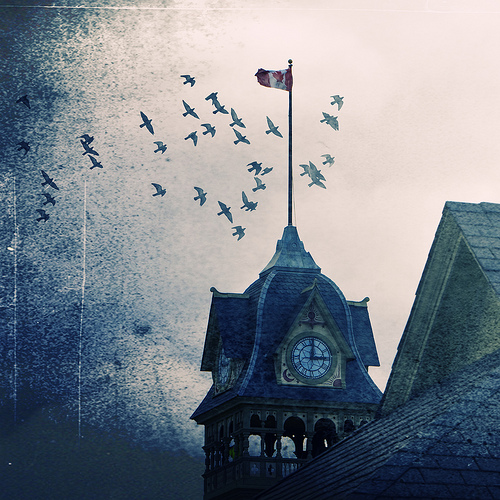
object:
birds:
[329, 94, 346, 111]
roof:
[370, 200, 500, 423]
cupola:
[187, 221, 388, 428]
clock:
[214, 336, 234, 397]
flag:
[253, 68, 295, 93]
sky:
[0, 0, 500, 500]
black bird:
[41, 169, 60, 190]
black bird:
[40, 193, 56, 207]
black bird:
[35, 208, 49, 223]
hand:
[310, 335, 315, 363]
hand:
[303, 356, 327, 361]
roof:
[251, 350, 500, 500]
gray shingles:
[428, 451, 483, 473]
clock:
[280, 297, 342, 388]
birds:
[180, 74, 197, 87]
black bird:
[150, 182, 167, 197]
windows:
[280, 415, 308, 460]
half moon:
[283, 368, 295, 382]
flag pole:
[287, 59, 294, 226]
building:
[187, 225, 387, 500]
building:
[258, 199, 499, 500]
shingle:
[476, 258, 500, 272]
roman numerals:
[295, 347, 301, 352]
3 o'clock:
[303, 337, 331, 362]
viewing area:
[201, 403, 357, 497]